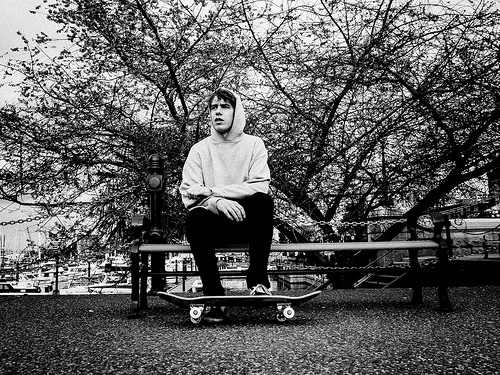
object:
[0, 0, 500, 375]
picture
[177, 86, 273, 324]
man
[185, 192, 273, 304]
pants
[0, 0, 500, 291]
trees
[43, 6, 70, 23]
leaves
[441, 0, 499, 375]
right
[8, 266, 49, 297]
boat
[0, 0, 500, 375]
background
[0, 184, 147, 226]
chain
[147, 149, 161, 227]
post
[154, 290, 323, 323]
skateboard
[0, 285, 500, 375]
ground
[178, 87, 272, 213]
jacket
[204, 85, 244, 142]
hood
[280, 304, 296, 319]
wheels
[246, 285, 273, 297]
feet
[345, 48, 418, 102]
branches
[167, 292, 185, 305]
rim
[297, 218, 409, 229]
chains